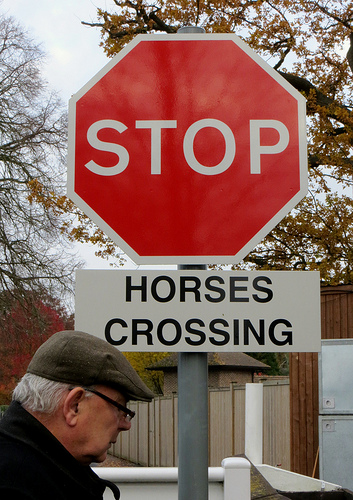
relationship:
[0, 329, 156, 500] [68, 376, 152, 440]
man wearing glasses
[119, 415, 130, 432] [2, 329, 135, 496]
nose of a person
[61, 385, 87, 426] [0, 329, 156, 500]
ear on man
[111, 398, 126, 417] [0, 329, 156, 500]
eye on man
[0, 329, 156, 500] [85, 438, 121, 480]
man has chin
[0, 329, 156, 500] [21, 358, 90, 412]
man has hair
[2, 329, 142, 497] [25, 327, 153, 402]
man wearing hat